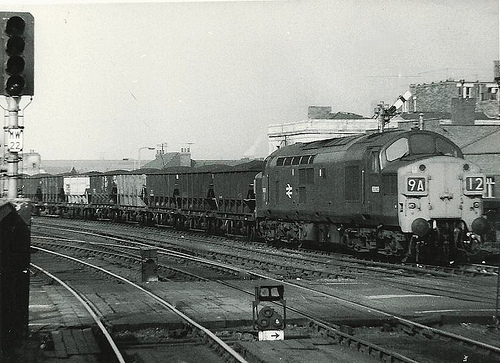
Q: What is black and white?
A: The photograph.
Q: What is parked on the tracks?
A: Train.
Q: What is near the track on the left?
A: Stop light.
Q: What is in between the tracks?
A: Dirt and gravel.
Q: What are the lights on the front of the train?
A: Headlights.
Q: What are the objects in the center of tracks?
A: Lights.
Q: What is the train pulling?
A: Cargo.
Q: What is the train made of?
A: Metal.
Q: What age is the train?
A: Old.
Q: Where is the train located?
A: Outside on the track.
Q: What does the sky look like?
A: Cloudy.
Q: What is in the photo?
A: A locomotive.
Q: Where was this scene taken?
A: New York.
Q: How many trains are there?
A: One.